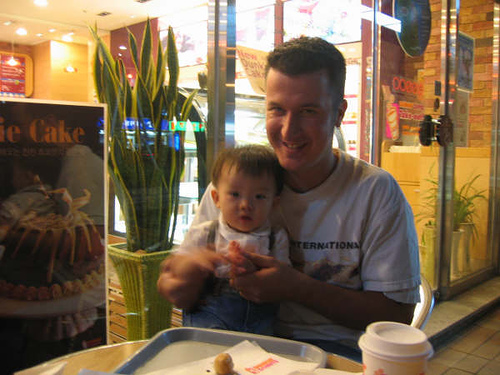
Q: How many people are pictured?
A: Two.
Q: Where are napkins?
A: On a tray.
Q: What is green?
A: Plants.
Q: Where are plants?
A: In a pot.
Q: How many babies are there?
A: One.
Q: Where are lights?
A: On the ceiling.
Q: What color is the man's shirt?
A: White.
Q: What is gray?
A: Tray.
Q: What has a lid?
A: A cup.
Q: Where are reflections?
A: On the glass.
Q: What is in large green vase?
A: Plant.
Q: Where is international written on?
A: Man's tee shirt.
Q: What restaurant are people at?
A: Dunkin donuts.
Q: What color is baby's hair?
A: Brown.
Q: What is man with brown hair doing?
A: Smiling.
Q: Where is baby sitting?
A: On man's lap.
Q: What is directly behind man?
A: Door to coffee shop.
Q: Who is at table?
A: Man and baby.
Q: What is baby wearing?
A: Blue jeans.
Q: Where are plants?
A: In a pot.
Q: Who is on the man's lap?
A: A baby.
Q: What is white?
A: Man's shirt.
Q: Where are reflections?
A: On glass.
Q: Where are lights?
A: On the ceiling.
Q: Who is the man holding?
A: A baby.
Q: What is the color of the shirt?
A: White.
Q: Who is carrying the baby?
A: A man.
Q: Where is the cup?
A: On the table.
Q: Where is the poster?
A: On the glass.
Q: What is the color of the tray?
A: Gray.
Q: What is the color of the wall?
A: Yellow.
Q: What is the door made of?
A: Glass.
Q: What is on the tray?
A: Dunkin donuts.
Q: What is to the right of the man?
A: A plant.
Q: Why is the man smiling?
A: He is happy.